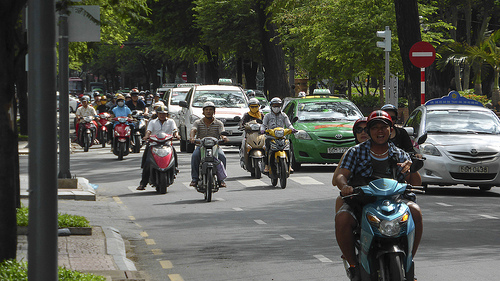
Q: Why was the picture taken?
A: To capture the people riding.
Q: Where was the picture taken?
A: On the street.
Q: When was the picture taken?
A: During the day.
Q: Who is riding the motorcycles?
A: People.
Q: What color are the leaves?
A: Green.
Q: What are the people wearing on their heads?
A: Helmets.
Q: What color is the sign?
A: Red and white.